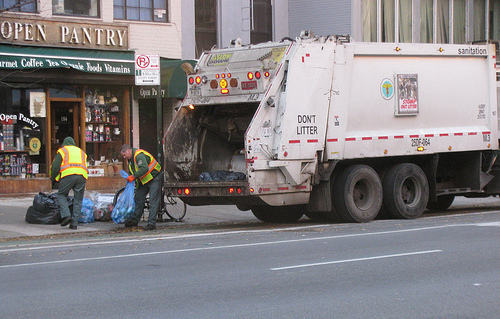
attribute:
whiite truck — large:
[162, 26, 492, 214]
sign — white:
[133, 52, 167, 91]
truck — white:
[163, 42, 498, 222]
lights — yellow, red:
[179, 69, 276, 89]